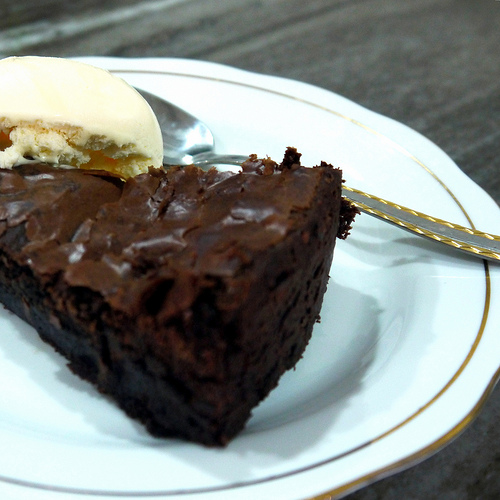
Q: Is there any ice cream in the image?
A: Yes, there is ice cream.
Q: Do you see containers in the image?
A: No, there are no containers.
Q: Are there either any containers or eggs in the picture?
A: No, there are no containers or eggs.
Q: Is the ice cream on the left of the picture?
A: Yes, the ice cream is on the left of the image.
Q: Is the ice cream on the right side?
A: No, the ice cream is on the left of the image.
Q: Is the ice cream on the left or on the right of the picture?
A: The ice cream is on the left of the image.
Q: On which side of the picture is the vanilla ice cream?
A: The ice cream is on the left of the image.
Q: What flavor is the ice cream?
A: That is a vanilla ice cream.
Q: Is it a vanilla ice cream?
A: Yes, that is a vanilla ice cream.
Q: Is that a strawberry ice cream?
A: No, that is a vanilla ice cream.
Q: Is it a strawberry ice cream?
A: No, that is a vanilla ice cream.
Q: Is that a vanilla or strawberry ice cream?
A: That is a vanilla ice cream.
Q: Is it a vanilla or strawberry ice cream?
A: That is a vanilla ice cream.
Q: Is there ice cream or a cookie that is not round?
A: No, there is ice cream but it is round.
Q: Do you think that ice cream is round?
A: Yes, the ice cream is round.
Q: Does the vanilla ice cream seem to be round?
A: Yes, the ice cream is round.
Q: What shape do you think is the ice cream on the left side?
A: The ice cream is round.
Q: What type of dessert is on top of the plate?
A: The dessert is ice cream.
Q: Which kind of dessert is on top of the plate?
A: The dessert is ice cream.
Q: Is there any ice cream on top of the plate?
A: Yes, there is ice cream on top of the plate.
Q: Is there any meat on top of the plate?
A: No, there is ice cream on top of the plate.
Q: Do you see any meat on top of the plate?
A: No, there is ice cream on top of the plate.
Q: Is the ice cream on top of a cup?
A: No, the ice cream is on top of the plate.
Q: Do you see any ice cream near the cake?
A: Yes, there is ice cream near the cake.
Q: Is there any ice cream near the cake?
A: Yes, there is ice cream near the cake.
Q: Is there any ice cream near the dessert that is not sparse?
A: Yes, there is ice cream near the cake.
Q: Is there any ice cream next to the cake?
A: Yes, there is ice cream next to the cake.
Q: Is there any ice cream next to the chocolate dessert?
A: Yes, there is ice cream next to the cake.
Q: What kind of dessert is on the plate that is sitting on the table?
A: The dessert is ice cream.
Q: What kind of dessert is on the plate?
A: The dessert is ice cream.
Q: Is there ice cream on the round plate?
A: Yes, there is ice cream on the plate.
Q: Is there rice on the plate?
A: No, there is ice cream on the plate.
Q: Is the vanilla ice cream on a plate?
A: Yes, the ice cream is on a plate.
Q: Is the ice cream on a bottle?
A: No, the ice cream is on a plate.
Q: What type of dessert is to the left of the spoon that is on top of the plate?
A: The dessert is ice cream.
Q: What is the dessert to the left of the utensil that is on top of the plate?
A: The dessert is ice cream.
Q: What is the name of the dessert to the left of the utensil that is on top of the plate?
A: The dessert is ice cream.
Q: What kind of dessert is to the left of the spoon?
A: The dessert is ice cream.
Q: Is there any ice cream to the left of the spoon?
A: Yes, there is ice cream to the left of the spoon.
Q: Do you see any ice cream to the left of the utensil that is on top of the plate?
A: Yes, there is ice cream to the left of the spoon.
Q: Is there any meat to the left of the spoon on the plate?
A: No, there is ice cream to the left of the spoon.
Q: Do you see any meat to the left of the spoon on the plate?
A: No, there is ice cream to the left of the spoon.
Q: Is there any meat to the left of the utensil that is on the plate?
A: No, there is ice cream to the left of the spoon.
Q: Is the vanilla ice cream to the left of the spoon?
A: Yes, the ice cream is to the left of the spoon.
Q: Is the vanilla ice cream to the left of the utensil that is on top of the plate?
A: Yes, the ice cream is to the left of the spoon.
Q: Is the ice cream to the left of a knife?
A: No, the ice cream is to the left of the spoon.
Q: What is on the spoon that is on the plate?
A: The ice cream is on the spoon.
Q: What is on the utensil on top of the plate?
A: The ice cream is on the spoon.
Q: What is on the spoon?
A: The ice cream is on the spoon.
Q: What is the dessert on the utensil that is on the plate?
A: The dessert is ice cream.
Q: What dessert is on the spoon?
A: The dessert is ice cream.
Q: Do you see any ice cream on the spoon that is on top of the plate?
A: Yes, there is ice cream on the spoon.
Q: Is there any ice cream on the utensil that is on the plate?
A: Yes, there is ice cream on the spoon.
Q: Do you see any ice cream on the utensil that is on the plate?
A: Yes, there is ice cream on the spoon.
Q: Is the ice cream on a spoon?
A: Yes, the ice cream is on a spoon.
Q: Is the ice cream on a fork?
A: No, the ice cream is on a spoon.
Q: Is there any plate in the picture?
A: Yes, there is a plate.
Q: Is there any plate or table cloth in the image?
A: Yes, there is a plate.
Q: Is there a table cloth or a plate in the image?
A: Yes, there is a plate.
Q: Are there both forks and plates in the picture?
A: No, there is a plate but no forks.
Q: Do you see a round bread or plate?
A: Yes, there is a round plate.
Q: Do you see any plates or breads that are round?
A: Yes, the plate is round.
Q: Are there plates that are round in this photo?
A: Yes, there is a round plate.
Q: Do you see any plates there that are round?
A: Yes, there is a plate that is round.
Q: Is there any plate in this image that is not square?
A: Yes, there is a round plate.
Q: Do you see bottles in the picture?
A: No, there are no bottles.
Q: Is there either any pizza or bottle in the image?
A: No, there are no bottles or pizzas.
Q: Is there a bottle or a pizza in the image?
A: No, there are no bottles or pizzas.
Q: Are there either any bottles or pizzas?
A: No, there are no bottles or pizzas.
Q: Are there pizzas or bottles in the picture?
A: No, there are no bottles or pizzas.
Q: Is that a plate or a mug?
A: That is a plate.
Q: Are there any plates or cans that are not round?
A: No, there is a plate but it is round.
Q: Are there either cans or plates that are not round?
A: No, there is a plate but it is round.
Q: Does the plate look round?
A: Yes, the plate is round.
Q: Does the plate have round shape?
A: Yes, the plate is round.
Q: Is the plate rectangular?
A: No, the plate is round.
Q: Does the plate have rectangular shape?
A: No, the plate is round.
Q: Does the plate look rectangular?
A: No, the plate is round.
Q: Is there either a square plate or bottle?
A: No, there is a plate but it is round.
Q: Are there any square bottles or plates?
A: No, there is a plate but it is round.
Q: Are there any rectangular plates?
A: No, there is a plate but it is round.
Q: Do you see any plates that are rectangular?
A: No, there is a plate but it is round.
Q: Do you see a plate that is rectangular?
A: No, there is a plate but it is round.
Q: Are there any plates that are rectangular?
A: No, there is a plate but it is round.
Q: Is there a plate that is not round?
A: No, there is a plate but it is round.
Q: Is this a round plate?
A: Yes, this is a round plate.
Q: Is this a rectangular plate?
A: No, this is a round plate.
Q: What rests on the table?
A: The plate rests on the table.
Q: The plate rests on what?
A: The plate rests on the table.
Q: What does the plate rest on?
A: The plate rests on the table.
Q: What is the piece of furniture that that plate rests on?
A: The piece of furniture is a table.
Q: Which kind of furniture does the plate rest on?
A: The plate rests on the table.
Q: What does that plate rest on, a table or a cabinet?
A: The plate rests on a table.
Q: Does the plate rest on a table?
A: Yes, the plate rests on a table.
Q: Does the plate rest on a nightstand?
A: No, the plate rests on a table.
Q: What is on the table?
A: The plate is on the table.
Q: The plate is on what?
A: The plate is on the table.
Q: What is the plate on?
A: The plate is on the table.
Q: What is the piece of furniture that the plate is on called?
A: The piece of furniture is a table.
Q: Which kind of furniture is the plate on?
A: The plate is on the table.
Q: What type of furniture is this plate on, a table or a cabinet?
A: The plate is on a table.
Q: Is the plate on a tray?
A: No, the plate is on the table.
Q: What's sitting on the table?
A: The plate is sitting on the table.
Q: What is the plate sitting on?
A: The plate is sitting on the table.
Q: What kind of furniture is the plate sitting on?
A: The plate is sitting on the table.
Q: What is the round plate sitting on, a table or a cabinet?
A: The plate is sitting on a table.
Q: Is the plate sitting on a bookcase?
A: No, the plate is sitting on a table.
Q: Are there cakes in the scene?
A: Yes, there is a cake.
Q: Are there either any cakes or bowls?
A: Yes, there is a cake.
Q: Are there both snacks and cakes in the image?
A: No, there is a cake but no snacks.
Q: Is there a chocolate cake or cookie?
A: Yes, there is a chocolate cake.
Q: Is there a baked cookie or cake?
A: Yes, there is a baked cake.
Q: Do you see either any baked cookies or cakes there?
A: Yes, there is a baked cake.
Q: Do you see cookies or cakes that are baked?
A: Yes, the cake is baked.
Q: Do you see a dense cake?
A: Yes, there is a dense cake.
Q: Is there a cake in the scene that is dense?
A: Yes, there is a cake that is dense.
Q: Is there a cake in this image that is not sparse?
A: Yes, there is a dense cake.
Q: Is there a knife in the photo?
A: No, there are no knives.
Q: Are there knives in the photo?
A: No, there are no knives.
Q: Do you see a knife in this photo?
A: No, there are no knives.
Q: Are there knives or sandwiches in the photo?
A: No, there are no knives or sandwiches.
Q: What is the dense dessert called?
A: The dessert is a cake.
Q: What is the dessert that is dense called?
A: The dessert is a cake.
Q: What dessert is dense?
A: The dessert is a cake.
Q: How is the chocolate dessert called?
A: The dessert is a cake.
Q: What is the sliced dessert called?
A: The dessert is a cake.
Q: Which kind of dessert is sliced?
A: The dessert is a cake.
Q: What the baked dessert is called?
A: The dessert is a cake.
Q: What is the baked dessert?
A: The dessert is a cake.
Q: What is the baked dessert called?
A: The dessert is a cake.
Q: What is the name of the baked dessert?
A: The dessert is a cake.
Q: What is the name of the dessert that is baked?
A: The dessert is a cake.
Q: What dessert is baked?
A: The dessert is a cake.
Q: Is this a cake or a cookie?
A: This is a cake.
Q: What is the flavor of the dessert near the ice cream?
A: This is a chocolate cake.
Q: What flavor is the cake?
A: This is a chocolate cake.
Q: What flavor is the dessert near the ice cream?
A: This is a chocolate cake.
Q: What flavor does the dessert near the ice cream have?
A: This is a chocolate cake.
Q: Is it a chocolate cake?
A: Yes, this is a chocolate cake.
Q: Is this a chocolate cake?
A: Yes, this is a chocolate cake.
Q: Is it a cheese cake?
A: No, this is a chocolate cake.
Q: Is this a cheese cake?
A: No, this is a chocolate cake.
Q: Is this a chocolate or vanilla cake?
A: This is a chocolate cake.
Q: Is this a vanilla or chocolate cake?
A: This is a chocolate cake.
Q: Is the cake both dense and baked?
A: Yes, the cake is dense and baked.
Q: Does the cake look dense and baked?
A: Yes, the cake is dense and baked.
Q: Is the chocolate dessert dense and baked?
A: Yes, the cake is dense and baked.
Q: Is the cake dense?
A: Yes, the cake is dense.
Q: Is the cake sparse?
A: No, the cake is dense.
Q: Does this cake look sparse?
A: No, the cake is dense.